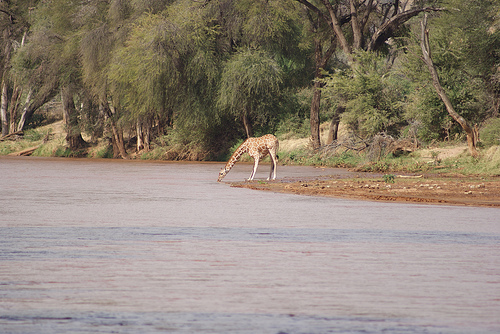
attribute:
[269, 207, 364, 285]
water — light blue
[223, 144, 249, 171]
neck — long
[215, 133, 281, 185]
giraffe — spotted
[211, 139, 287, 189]
giraffe — spotted, yellow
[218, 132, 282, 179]
giraffe — alone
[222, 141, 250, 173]
giraffe's neck — bent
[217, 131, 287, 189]
giraffe — spotted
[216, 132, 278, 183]
giraffe — long , butt , spotted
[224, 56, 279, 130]
tree — green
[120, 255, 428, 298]
water — clean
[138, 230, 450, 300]
water — beautiful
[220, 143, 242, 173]
neck — long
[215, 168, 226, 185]
head — looking down